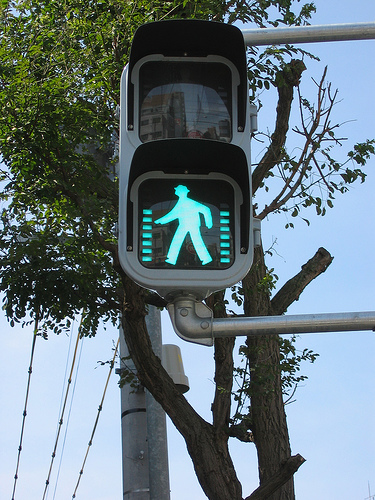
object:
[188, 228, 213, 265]
pants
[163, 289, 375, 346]
pole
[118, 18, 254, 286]
light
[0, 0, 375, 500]
tree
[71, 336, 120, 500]
lines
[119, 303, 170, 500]
pole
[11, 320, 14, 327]
leaves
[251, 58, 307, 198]
branches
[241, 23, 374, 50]
pole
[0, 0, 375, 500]
sky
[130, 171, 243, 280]
signal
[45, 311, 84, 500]
wire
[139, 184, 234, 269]
sign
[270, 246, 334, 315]
branch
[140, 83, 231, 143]
city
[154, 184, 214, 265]
man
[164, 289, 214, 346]
joint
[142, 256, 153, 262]
dashes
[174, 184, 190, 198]
head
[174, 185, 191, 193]
hat